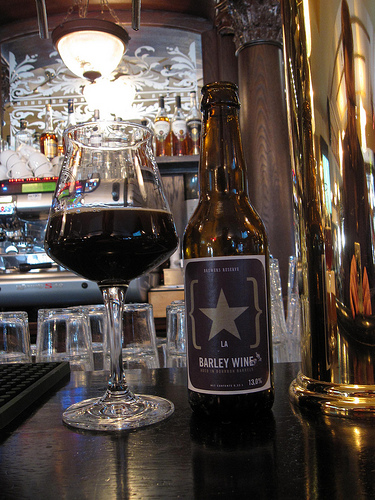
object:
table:
[0, 360, 374, 499]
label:
[183, 252, 273, 395]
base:
[61, 385, 176, 434]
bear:
[186, 79, 278, 420]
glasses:
[0, 309, 31, 365]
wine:
[45, 205, 178, 289]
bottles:
[13, 113, 31, 150]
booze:
[153, 93, 174, 158]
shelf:
[152, 150, 200, 175]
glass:
[42, 118, 178, 434]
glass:
[205, 183, 233, 242]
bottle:
[180, 79, 276, 423]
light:
[57, 31, 125, 90]